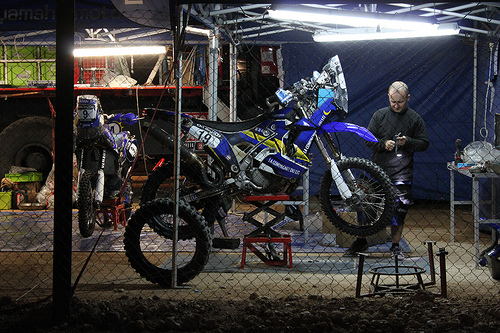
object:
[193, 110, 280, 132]
seat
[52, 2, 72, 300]
pole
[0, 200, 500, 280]
ground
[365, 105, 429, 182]
shirt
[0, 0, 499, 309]
chainlink fence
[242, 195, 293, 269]
jack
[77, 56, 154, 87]
supplies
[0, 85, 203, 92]
shelf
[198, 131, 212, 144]
19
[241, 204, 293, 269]
lift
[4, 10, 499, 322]
fencing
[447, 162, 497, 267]
table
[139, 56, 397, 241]
bike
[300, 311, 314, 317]
pebbles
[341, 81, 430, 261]
man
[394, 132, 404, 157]
light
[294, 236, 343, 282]
mesh wire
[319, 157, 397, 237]
front tire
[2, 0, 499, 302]
carport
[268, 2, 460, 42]
fluorescent light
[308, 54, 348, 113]
bug shield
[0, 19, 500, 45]
roof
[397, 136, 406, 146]
man's hand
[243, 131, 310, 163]
stripe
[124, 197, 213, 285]
tire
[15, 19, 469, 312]
picture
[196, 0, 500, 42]
ceiling